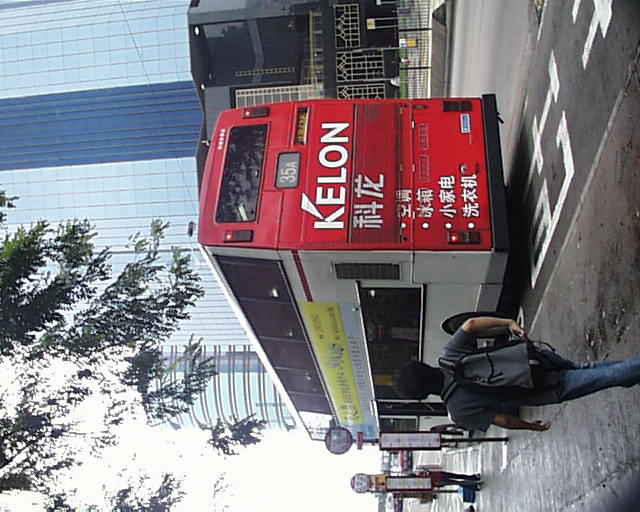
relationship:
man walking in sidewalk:
[392, 303, 636, 453] [398, 399, 612, 503]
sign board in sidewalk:
[321, 421, 444, 491] [433, 72, 635, 508]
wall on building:
[1, 154, 213, 255] [5, 3, 416, 356]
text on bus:
[306, 112, 357, 236] [176, 91, 515, 452]